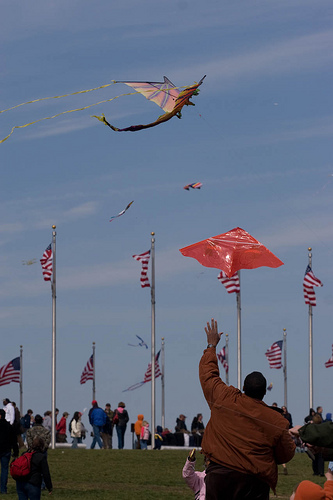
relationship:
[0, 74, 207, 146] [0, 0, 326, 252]
dragon kite on air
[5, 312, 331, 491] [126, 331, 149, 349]
people watching kite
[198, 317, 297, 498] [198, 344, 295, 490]
man wearing jacket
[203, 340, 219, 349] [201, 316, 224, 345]
watch in hand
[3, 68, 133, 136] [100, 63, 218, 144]
ribbons hanging from kite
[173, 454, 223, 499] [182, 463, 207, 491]
child wearing jacket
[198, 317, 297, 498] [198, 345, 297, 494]
man with brown jacket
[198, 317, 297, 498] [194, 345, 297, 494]
man in brown jacket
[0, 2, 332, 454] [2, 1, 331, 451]
sky has clouds